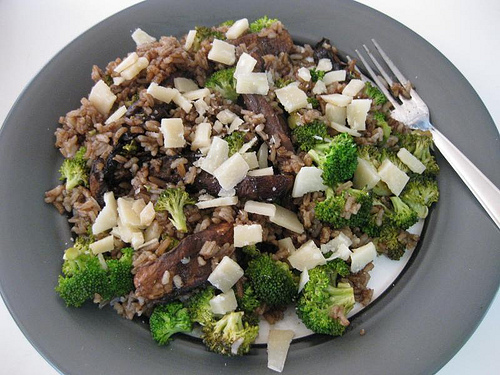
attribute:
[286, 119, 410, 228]
broccoli — piece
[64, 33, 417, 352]
food — piece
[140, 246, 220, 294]
meat — piece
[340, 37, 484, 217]
forks — metal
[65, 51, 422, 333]
food — pile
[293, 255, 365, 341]
broccoli — dark, green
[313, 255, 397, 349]
broccoli — piece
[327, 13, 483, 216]
fork — metal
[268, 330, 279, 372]
onion — piece, white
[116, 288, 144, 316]
rice — brown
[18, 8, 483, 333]
plate — round, gray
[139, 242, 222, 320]
meat — cooked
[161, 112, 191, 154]
cheese — white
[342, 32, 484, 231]
fork — silver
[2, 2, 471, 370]
plate — gray, round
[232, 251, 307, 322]
broccoli — green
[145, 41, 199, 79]
rice — brown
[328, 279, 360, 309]
stalk — green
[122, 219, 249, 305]
meat — brown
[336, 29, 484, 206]
fork — large, metal, silver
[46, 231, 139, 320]
broccoli — green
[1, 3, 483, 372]
table — white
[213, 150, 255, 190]
cheese — white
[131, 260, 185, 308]
meat — brown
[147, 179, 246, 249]
rice — brown